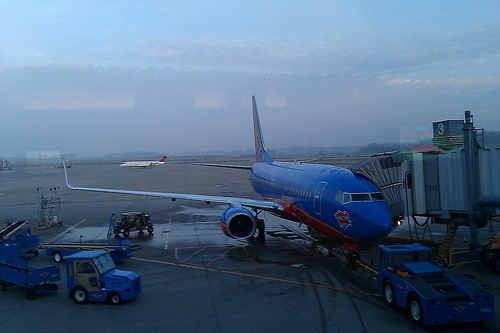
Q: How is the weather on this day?
A: It is overcast.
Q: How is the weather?
A: It is overcast.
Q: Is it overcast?
A: Yes, it is overcast.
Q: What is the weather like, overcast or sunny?
A: It is overcast.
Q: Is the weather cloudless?
A: No, it is overcast.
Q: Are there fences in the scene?
A: No, there are no fences.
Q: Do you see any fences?
A: No, there are no fences.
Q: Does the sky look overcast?
A: Yes, the sky is overcast.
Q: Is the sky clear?
A: No, the sky is overcast.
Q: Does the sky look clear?
A: No, the sky is overcast.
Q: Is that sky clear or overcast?
A: The sky is overcast.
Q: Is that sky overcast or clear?
A: The sky is overcast.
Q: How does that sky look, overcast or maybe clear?
A: The sky is overcast.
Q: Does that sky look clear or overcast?
A: The sky is overcast.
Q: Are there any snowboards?
A: No, there are no snowboards.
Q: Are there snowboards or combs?
A: No, there are no snowboards or combs.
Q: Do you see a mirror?
A: No, there are no mirrors.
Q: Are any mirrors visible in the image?
A: No, there are no mirrors.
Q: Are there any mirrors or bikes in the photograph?
A: No, there are no mirrors or bikes.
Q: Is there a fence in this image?
A: No, there are no fences.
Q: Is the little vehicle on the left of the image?
A: Yes, the vehicle is on the left of the image.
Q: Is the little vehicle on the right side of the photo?
A: No, the vehicle is on the left of the image.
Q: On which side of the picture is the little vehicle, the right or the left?
A: The vehicle is on the left of the image.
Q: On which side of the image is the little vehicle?
A: The vehicle is on the left of the image.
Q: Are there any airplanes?
A: Yes, there is an airplane.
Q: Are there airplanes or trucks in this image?
A: Yes, there is an airplane.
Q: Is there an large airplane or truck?
A: Yes, there is a large airplane.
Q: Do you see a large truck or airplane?
A: Yes, there is a large airplane.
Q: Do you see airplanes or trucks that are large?
A: Yes, the airplane is large.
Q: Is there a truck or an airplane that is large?
A: Yes, the airplane is large.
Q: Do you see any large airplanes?
A: Yes, there is a large airplane.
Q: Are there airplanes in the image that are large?
A: Yes, there is an airplane that is large.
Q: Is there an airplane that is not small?
A: Yes, there is a large airplane.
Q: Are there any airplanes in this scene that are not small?
A: Yes, there is a large airplane.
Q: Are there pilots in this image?
A: No, there are no pilots.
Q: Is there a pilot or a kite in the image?
A: No, there are no pilots or kites.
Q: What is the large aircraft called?
A: The aircraft is an airplane.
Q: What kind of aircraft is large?
A: The aircraft is an airplane.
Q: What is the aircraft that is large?
A: The aircraft is an airplane.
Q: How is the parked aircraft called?
A: The aircraft is an airplane.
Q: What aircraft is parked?
A: The aircraft is an airplane.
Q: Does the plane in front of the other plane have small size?
A: No, the airplane is large.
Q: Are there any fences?
A: No, there are no fences.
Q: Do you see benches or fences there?
A: No, there are no fences or benches.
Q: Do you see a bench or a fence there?
A: No, there are no fences or benches.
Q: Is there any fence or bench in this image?
A: No, there are no fences or benches.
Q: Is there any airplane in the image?
A: Yes, there is an airplane.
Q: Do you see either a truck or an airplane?
A: Yes, there is an airplane.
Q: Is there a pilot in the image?
A: No, there are no pilots.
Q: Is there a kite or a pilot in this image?
A: No, there are no pilots or kites.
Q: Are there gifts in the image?
A: No, there are no gifts.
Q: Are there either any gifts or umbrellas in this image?
A: No, there are no gifts or umbrellas.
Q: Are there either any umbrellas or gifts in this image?
A: No, there are no gifts or umbrellas.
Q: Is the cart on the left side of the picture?
A: No, the cart is on the right of the image.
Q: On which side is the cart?
A: The cart is on the right of the image.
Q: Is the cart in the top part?
A: No, the cart is in the bottom of the image.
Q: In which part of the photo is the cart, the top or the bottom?
A: The cart is in the bottom of the image.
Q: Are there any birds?
A: No, there are no birds.